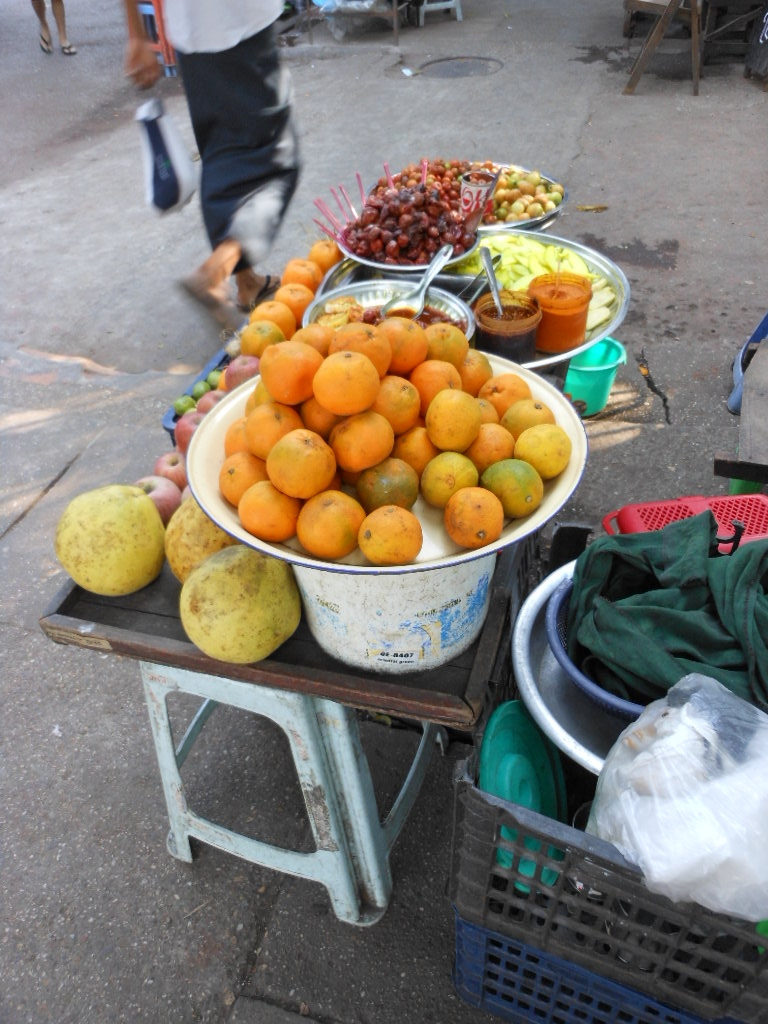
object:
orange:
[311, 347, 383, 416]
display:
[174, 243, 580, 607]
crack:
[56, 518, 126, 573]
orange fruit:
[217, 306, 574, 561]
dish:
[186, 347, 592, 672]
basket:
[447, 520, 768, 1021]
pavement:
[4, 3, 766, 1022]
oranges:
[219, 310, 576, 562]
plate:
[178, 312, 590, 580]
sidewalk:
[6, 6, 767, 1022]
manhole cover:
[419, 54, 504, 79]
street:
[4, 2, 745, 1020]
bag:
[131, 80, 196, 219]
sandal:
[184, 273, 244, 328]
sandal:
[235, 273, 278, 312]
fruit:
[56, 121, 631, 676]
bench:
[129, 643, 452, 927]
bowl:
[302, 280, 476, 341]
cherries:
[311, 161, 472, 263]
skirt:
[178, 35, 304, 248]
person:
[119, 0, 302, 325]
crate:
[448, 515, 745, 1022]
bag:
[580, 668, 767, 923]